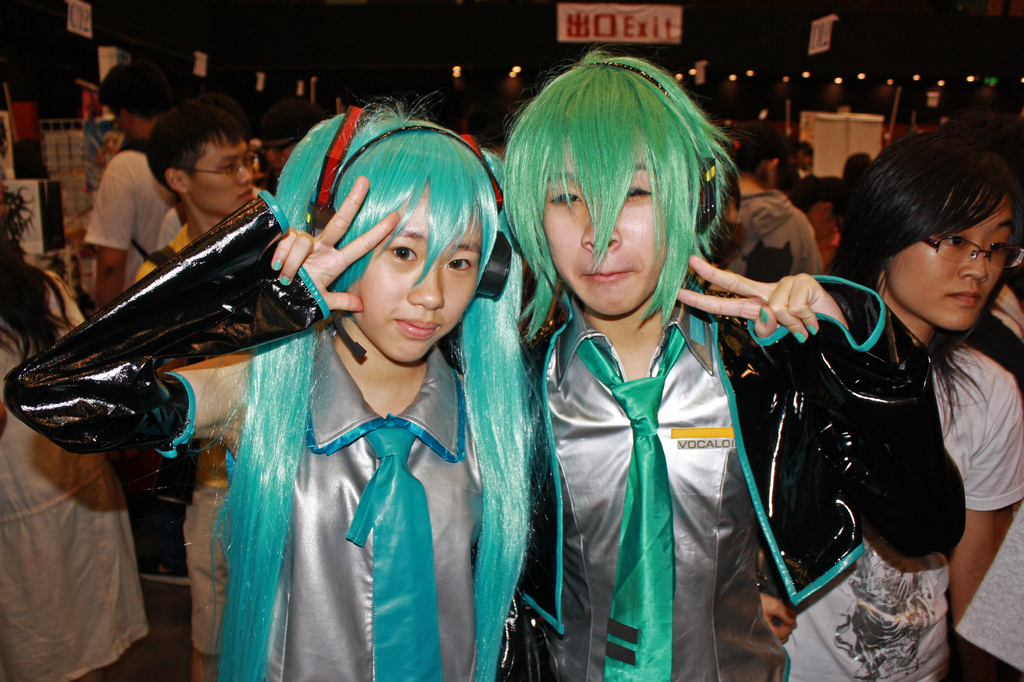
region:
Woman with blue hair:
[212, 102, 538, 679]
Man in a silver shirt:
[541, 300, 788, 680]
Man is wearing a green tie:
[576, 316, 691, 680]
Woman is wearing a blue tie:
[345, 417, 438, 680]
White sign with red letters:
[554, 3, 682, 43]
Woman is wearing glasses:
[920, 227, 1022, 270]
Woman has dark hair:
[826, 126, 1020, 421]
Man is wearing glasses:
[175, 149, 258, 182]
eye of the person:
[441, 255, 483, 276]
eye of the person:
[542, 184, 572, 211]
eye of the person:
[605, 180, 651, 210]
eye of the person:
[912, 221, 957, 245]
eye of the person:
[962, 233, 1001, 265]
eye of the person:
[241, 146, 261, 170]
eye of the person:
[210, 157, 234, 173]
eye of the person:
[750, 149, 754, 176]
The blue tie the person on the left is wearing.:
[356, 430, 440, 675]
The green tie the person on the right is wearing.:
[596, 351, 674, 675]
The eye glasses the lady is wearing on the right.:
[901, 225, 1015, 268]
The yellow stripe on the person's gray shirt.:
[661, 424, 737, 444]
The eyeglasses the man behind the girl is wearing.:
[196, 155, 257, 181]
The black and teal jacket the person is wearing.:
[517, 281, 961, 614]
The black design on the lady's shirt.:
[819, 538, 921, 675]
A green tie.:
[576, 326, 688, 681]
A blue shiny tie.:
[346, 421, 444, 681]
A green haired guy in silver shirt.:
[498, 52, 966, 681]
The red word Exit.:
[618, 11, 676, 41]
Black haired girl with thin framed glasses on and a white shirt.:
[757, 125, 1020, 680]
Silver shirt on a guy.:
[531, 293, 795, 680]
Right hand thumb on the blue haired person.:
[320, 292, 366, 312]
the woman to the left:
[27, 101, 555, 665]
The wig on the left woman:
[251, 107, 527, 307]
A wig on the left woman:
[255, 99, 518, 277]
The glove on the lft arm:
[15, 187, 319, 450]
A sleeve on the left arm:
[28, 171, 314, 443]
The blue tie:
[341, 414, 481, 674]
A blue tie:
[325, 412, 471, 673]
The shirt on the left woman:
[227, 345, 507, 674]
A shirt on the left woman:
[224, 330, 537, 669]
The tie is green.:
[606, 376, 702, 670]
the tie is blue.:
[356, 395, 448, 627]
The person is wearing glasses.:
[186, 139, 275, 174]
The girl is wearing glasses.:
[923, 225, 1006, 271]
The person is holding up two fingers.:
[306, 183, 393, 260]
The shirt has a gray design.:
[852, 535, 952, 663]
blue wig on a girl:
[233, 102, 540, 668]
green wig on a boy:
[497, 71, 728, 335]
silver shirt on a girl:
[252, 348, 494, 675]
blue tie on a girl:
[352, 421, 460, 679]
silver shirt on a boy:
[498, 317, 792, 679]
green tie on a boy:
[574, 341, 705, 665]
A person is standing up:
[508, 84, 825, 676]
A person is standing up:
[40, 124, 524, 663]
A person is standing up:
[699, 117, 795, 318]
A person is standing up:
[797, 179, 859, 282]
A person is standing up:
[793, 136, 816, 184]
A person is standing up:
[119, 122, 233, 269]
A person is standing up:
[249, 93, 322, 177]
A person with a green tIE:
[554, 72, 755, 671]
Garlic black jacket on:
[470, 145, 888, 627]